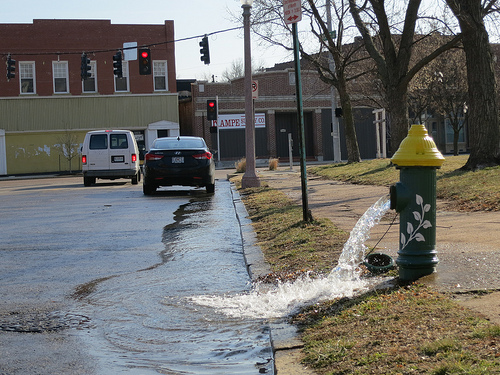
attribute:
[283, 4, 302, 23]
sign — TRAFFIC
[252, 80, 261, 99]
sign — TRAFFIC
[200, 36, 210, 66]
lights — TRAFFIC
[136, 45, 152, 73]
lights — TRAFFIC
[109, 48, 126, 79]
lights — TRAFFIC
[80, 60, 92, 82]
lights — TRAFFIC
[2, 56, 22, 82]
lights — TRAFFIC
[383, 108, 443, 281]
hydrant — GREEN, YELLOW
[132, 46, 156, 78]
light — RED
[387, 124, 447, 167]
top — YELLOW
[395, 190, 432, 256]
plant — WHITE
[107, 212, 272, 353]
puddle — LARGE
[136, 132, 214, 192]
car — SMALL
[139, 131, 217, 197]
car — SMALL, BLACK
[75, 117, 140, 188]
van — WHITE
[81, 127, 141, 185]
van — white